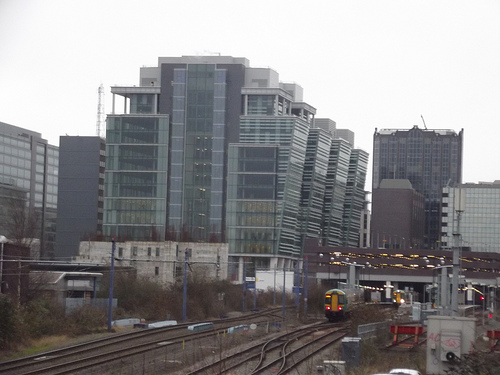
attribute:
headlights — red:
[337, 306, 342, 312]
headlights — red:
[325, 305, 329, 311]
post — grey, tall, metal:
[104, 239, 117, 334]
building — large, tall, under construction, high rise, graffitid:
[103, 55, 370, 295]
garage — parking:
[302, 242, 500, 283]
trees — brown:
[2, 193, 46, 323]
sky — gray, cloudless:
[1, 2, 500, 215]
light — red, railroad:
[478, 294, 485, 300]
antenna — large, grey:
[96, 86, 103, 139]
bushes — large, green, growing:
[2, 290, 108, 356]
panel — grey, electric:
[425, 308, 480, 374]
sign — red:
[390, 323, 424, 336]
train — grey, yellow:
[327, 281, 373, 322]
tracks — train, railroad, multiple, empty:
[180, 307, 411, 374]